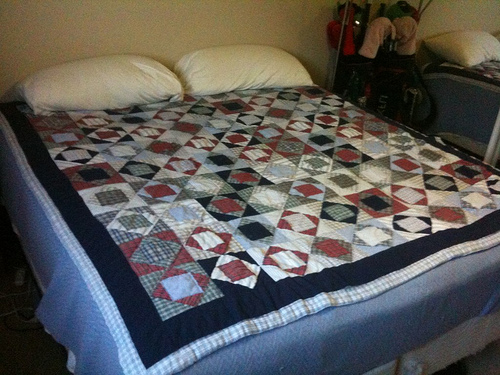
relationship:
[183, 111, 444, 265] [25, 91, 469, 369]
quilt on bed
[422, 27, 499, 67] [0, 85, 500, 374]
pillow on bed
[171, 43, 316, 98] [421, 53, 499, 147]
pillow on bed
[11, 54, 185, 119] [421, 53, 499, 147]
pillow on bed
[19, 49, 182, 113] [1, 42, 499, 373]
pillow on bed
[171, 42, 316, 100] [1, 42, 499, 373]
pillow on bed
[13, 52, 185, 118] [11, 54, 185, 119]
case on pillow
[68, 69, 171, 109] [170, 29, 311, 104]
case on pillow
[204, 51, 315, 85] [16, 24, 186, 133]
case on pillow